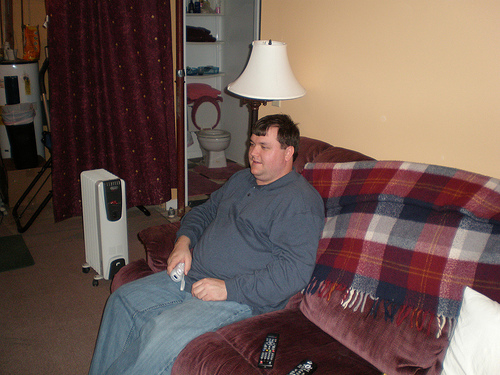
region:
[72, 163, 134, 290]
white and black radiator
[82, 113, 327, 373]
man wearing jeans and a shirt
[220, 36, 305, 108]
white lamp shade on a lamp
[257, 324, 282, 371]
remote control made of black plastic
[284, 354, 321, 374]
remote control made of black plastic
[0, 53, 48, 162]
black and white water heater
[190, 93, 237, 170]
toilet with red cover on it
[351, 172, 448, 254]
a blanket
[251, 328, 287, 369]
a controller on the couch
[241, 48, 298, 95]
a lamp shade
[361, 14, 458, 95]
the wall is brown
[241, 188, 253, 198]
a button on the shirt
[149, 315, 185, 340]
blue jeans the man is wearing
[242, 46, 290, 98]
the lampshade is white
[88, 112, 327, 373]
the man is sitting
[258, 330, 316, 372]
the remotes on the sofa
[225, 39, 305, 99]
the white lamp shade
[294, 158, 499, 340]
the blanket on the sofa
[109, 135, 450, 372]
the sofa the man is sitting on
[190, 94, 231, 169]
the toilet in the background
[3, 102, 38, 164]
the trash can near the water heater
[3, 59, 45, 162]
the water heater behind the trash can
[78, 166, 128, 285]
the white object near the man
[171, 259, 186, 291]
the wiimote in the man's hand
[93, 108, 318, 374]
This is a person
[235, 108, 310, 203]
Head of a person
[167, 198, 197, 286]
Hand of a person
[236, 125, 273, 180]
Face of a person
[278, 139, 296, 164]
Ear of a person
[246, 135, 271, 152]
Eyes of a person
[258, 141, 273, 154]
Eye of a person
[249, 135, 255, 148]
Eye of a person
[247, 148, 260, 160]
Nose of a person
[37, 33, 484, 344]
this is a man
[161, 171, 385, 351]
the shirt is long sleeved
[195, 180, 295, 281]
the shirt is gray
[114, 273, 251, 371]
this is blue jeans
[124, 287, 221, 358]
the jeans are baggy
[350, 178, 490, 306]
the blanket is draped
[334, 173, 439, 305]
the blanket is wool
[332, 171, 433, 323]
the blanket is flannel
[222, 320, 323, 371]
these are remote controls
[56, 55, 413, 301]
this is a living room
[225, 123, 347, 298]
this is a man